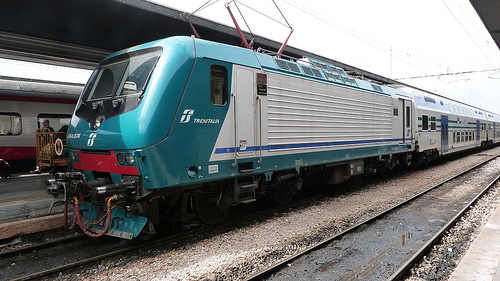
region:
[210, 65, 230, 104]
window on the train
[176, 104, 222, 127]
logo on the train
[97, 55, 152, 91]
windshild on the train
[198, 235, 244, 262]
small rocks on the ground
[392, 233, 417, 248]
a puddle of water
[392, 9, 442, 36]
the sky is clear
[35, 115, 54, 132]
a person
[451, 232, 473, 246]
rocks on the ground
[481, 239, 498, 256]
the sidewalk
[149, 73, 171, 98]
light on the train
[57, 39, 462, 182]
the train at the platform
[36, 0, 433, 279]
the train at the platform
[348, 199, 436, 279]
a puddle of water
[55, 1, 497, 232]
A blue and silver commuter train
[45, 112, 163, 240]
Red trim on front of train engine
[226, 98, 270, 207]
Pair of steps on side of train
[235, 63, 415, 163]
Silver colored door and side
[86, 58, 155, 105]
A glass windshield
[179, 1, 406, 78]
Red rails on top of train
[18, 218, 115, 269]
Train tracks on ground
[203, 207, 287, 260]
Gravel between tracks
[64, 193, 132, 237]
Red hose hanging down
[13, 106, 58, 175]
People on other side of train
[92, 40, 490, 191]
train on the track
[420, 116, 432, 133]
window on the train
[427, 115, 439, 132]
window on the train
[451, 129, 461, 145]
window on the train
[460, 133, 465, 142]
window on the train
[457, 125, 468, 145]
window on the train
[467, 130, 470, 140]
window on the train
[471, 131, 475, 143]
window on the train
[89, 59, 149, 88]
window on the train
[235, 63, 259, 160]
the door on the train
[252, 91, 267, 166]
the rail on the train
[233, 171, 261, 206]
the steps to the train door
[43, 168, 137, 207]
the bumper on the front of the train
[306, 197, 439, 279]
the train tracke on the wet ground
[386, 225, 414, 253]
the water puddle in between the tracks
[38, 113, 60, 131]
the head of the man on thr platform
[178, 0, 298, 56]
the red frame for the wires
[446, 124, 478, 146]
the line of windows on the train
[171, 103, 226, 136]
the logo on the front of the train